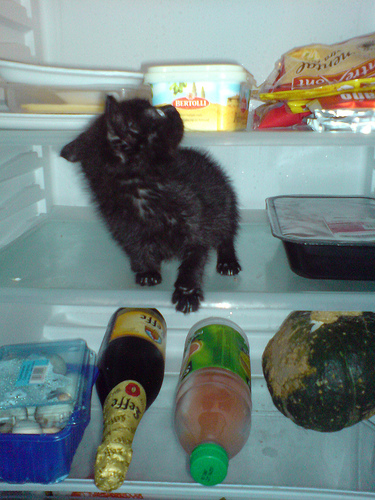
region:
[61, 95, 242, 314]
black kitten with wet fur, light blue eyes with head turned toward its back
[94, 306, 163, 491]
sealed wine bottle with Seffe on label, gold foil top and gold label with picture, brown bottle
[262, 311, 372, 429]
round, green squash with yellow specks and tan top and dirty left side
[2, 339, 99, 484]
blue box with clear lid and assorted things inside it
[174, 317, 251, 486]
clear plastic bottle with orange-pinkish liquid inside and green lid and label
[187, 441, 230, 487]
green bottle lid with writing on it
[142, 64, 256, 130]
square box with Bertolli on it with yellow, white, blue and other colors on it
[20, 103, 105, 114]
yellowish dish setting alone on a shelf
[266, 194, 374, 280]
square black box with clear plastic top and a red and white paper inside it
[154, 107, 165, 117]
light blue eye on a black kitten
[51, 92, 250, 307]
the kitten is in the fridge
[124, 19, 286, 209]
the interior is white in colour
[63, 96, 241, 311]
the cat is black in colour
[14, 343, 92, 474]
the crate is blue in colour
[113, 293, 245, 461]
bottles are on their side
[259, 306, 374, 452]
the pumpkin is near the bottles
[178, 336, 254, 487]
the bottle has a juice inside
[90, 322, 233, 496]
the bottles are sealed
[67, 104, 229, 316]
the cat is standing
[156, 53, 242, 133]
the pack is white in colour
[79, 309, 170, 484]
bottle of leffe in fridge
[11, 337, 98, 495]
container of mushrooms on left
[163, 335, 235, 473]
plastic bottle in fridge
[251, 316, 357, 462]
lobster tail on right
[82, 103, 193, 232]
small kitten in fridge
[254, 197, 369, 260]
sealed plastic food container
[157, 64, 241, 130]
small container on top shelf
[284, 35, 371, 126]
bags of chips on top shelf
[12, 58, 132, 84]
white plate on top shelf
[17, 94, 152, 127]
yellow food between plates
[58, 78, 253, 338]
black kitten in a fridge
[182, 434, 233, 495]
green cap on a bottle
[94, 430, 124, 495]
gold foil top of a bottle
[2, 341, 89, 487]
container of mushrooms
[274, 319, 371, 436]
gross bottom of a vegetable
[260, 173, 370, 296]
black container with plastic lid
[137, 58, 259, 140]
plastic container of butter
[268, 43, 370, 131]
bags of tortillas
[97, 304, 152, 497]
bottle of champagne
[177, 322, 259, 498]
bottle of juice with a green label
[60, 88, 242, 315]
black dog into a fridge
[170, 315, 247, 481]
green bottle with orange juice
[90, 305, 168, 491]
wine bottle into a fridge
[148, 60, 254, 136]
butter pot into a fridge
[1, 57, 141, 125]
cheese plates into a fridge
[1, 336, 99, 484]
blue box with candies inside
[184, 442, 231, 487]
green plastic cover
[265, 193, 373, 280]
vacuum sealed tray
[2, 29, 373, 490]
food into a fridge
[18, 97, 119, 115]
yellow cheese plate